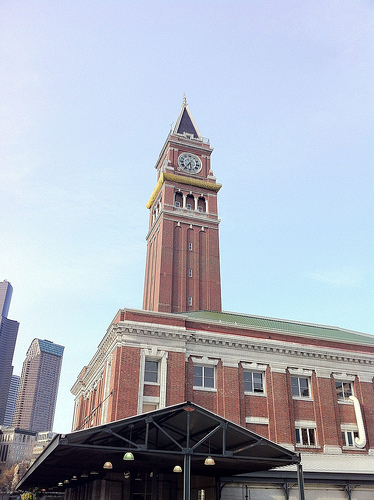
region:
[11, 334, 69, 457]
tall building in the city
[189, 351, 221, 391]
windows of a building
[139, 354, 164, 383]
windows of a building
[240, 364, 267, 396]
slightly opened windows of a building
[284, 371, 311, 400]
windows of a building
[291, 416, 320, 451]
an opened window of a building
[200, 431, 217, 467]
lamps hanged on ceiling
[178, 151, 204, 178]
clock of a building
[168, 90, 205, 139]
roof of a building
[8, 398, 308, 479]
ceiling of a building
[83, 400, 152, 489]
this is a pavillion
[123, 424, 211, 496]
the pavilion is black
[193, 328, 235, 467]
this is a window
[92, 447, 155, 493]
this is a light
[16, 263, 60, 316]
this is a cloud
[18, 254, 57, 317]
the cloud is white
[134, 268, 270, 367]
this is a tower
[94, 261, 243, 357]
this is a clock tower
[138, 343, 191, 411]
this is a brick building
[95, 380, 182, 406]
the building is red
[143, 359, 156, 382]
window on brick building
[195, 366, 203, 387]
window on brick building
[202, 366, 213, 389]
window on brick building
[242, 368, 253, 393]
window on brick building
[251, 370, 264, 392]
window on brick building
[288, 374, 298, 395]
window on brick building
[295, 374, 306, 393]
window on brick building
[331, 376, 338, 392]
window on brick building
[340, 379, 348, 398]
window on brick building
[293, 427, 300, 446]
window on brick building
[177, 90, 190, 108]
weather vane on top of tower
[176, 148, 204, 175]
clock on front of tower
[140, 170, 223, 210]
yellow concrete divider on tower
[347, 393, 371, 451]
white hose running out of window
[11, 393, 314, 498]
black awning in front of building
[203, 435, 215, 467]
light hanging from ceiling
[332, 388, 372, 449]
hose running to bottom window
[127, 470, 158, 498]
door under awning is entrance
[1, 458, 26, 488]
trees are in front of buildings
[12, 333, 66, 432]
tall office in the distance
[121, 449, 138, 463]
Electrical light unit underneath ceiling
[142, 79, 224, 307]
Brick clock tower on building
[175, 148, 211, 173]
Clock face on the building's clock tower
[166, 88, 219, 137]
Pointed steeple on top of the clock tower building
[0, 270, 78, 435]
Several skyscrapers in the background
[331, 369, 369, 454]
Two windows connected by a white tube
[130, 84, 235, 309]
Clock tower on top of building made out of brick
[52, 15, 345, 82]
Clear blue skies with no clouds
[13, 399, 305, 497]
Outdoor covered area with lights underneath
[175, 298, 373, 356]
Green roof on top of the building made of brick